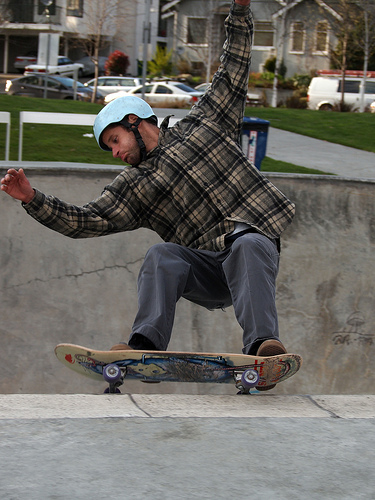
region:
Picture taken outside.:
[17, 27, 338, 495]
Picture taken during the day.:
[31, 55, 243, 497]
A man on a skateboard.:
[64, 88, 291, 386]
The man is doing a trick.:
[25, 18, 319, 421]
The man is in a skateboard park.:
[21, 21, 337, 467]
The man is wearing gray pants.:
[135, 241, 297, 370]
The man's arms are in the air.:
[17, 24, 280, 240]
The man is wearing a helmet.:
[78, 68, 169, 148]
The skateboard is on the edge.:
[35, 255, 355, 431]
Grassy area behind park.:
[21, 113, 152, 168]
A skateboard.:
[51, 342, 301, 398]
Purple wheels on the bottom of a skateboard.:
[88, 363, 258, 394]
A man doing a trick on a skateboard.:
[3, 2, 303, 439]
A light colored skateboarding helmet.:
[92, 93, 155, 153]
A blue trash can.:
[243, 116, 268, 171]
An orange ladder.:
[314, 65, 373, 76]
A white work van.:
[304, 67, 373, 117]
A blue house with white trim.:
[156, 1, 343, 92]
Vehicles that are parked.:
[3, 48, 372, 134]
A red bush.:
[103, 48, 131, 76]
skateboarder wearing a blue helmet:
[22, 14, 372, 443]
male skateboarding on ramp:
[5, 35, 333, 443]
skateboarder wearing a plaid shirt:
[7, 72, 318, 357]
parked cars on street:
[0, 64, 213, 110]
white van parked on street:
[303, 56, 374, 116]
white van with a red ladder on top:
[304, 69, 372, 105]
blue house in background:
[160, 2, 340, 82]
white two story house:
[0, 3, 154, 82]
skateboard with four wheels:
[46, 333, 322, 395]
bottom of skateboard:
[49, 353, 307, 388]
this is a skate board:
[47, 318, 306, 409]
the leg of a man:
[219, 226, 306, 386]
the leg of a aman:
[118, 218, 221, 367]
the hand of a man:
[0, 164, 139, 238]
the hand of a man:
[190, 0, 256, 118]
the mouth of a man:
[121, 151, 130, 167]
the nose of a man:
[110, 146, 123, 158]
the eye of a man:
[108, 133, 124, 147]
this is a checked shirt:
[26, 8, 309, 248]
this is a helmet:
[82, 91, 161, 153]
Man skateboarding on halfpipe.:
[0, 0, 302, 395]